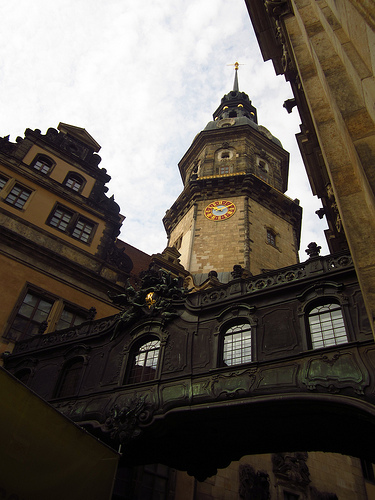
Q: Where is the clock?
A: On the clock tower.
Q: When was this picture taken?
A: 10:10.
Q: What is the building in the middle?
A: Walkway.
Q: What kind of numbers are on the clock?
A: Roman.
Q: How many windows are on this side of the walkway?
A: 4.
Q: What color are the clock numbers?
A: Gold.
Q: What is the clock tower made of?
A: Stone.